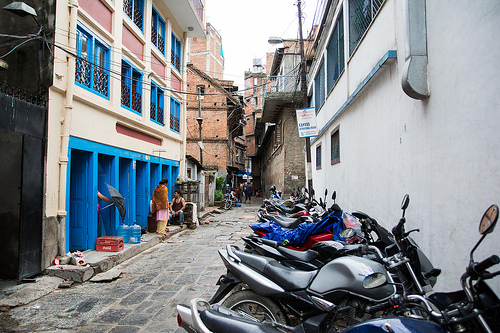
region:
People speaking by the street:
[146, 175, 188, 238]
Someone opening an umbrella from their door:
[85, 178, 128, 250]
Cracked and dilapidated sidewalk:
[45, 246, 122, 304]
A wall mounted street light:
[0, 3, 44, 24]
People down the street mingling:
[208, 169, 267, 214]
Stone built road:
[113, 255, 191, 332]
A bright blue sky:
[217, 1, 277, 46]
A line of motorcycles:
[214, 200, 441, 327]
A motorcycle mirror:
[475, 200, 497, 235]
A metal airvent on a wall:
[390, 0, 444, 112]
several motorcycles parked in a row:
[192, 172, 468, 331]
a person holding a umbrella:
[101, 181, 128, 227]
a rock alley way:
[132, 210, 235, 332]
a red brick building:
[190, 80, 222, 173]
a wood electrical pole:
[288, 8, 307, 97]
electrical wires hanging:
[188, 18, 313, 128]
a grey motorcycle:
[242, 251, 407, 301]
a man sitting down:
[172, 186, 185, 218]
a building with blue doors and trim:
[33, 148, 185, 268]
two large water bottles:
[113, 217, 148, 249]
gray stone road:
[4, 161, 279, 323]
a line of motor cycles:
[197, 163, 499, 331]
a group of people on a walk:
[147, 177, 186, 239]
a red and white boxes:
[93, 234, 124, 251]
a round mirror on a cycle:
[472, 203, 497, 235]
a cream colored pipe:
[60, 85, 73, 221]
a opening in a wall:
[112, 115, 172, 146]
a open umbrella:
[96, 181, 129, 221]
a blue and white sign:
[294, 107, 321, 138]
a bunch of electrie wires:
[194, 63, 296, 103]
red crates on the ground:
[94, 235, 124, 254]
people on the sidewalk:
[152, 176, 189, 236]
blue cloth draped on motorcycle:
[275, 220, 309, 242]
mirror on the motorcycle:
[464, 195, 499, 238]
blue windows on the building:
[72, 23, 110, 94]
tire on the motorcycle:
[230, 285, 257, 315]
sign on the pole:
[293, 107, 316, 142]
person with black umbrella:
[95, 180, 127, 227]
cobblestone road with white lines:
[133, 274, 160, 330]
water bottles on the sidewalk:
[118, 221, 142, 244]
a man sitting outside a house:
[167, 157, 193, 228]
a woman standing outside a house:
[146, 155, 166, 235]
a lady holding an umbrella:
[96, 179, 126, 246]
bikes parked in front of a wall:
[175, 180, 497, 319]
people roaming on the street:
[224, 164, 260, 214]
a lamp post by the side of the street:
[195, 84, 230, 228]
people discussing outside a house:
[145, 153, 194, 244]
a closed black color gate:
[3, 85, 75, 302]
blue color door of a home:
[67, 130, 97, 275]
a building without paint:
[187, 61, 244, 207]